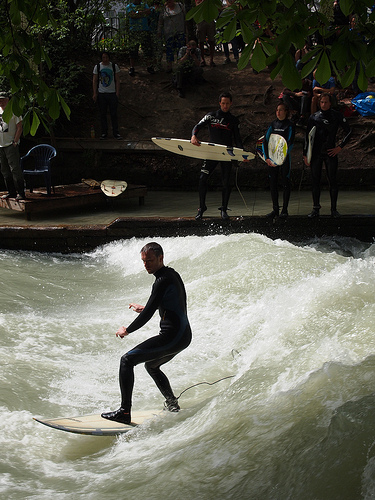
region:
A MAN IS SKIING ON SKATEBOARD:
[28, 236, 195, 435]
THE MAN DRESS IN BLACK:
[100, 241, 195, 422]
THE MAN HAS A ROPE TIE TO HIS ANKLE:
[160, 372, 238, 411]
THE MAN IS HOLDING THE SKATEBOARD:
[150, 134, 257, 163]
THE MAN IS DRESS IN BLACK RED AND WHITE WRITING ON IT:
[189, 91, 247, 221]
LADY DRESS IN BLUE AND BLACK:
[253, 102, 293, 224]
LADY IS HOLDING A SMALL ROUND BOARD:
[250, 132, 289, 169]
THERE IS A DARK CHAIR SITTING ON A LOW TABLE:
[18, 143, 57, 192]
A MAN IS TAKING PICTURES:
[171, 35, 208, 95]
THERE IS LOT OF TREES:
[0, 1, 374, 137]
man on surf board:
[24, 229, 227, 441]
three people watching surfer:
[141, 86, 359, 223]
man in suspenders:
[84, 48, 130, 143]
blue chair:
[14, 137, 62, 197]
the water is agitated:
[193, 222, 374, 448]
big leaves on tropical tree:
[222, 36, 374, 89]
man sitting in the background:
[173, 36, 213, 96]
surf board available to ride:
[79, 163, 144, 212]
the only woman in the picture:
[250, 93, 305, 229]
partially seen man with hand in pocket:
[1, 82, 32, 205]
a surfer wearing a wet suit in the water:
[97, 232, 200, 432]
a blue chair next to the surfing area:
[11, 136, 63, 196]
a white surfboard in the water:
[27, 401, 170, 443]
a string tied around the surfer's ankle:
[163, 380, 251, 407]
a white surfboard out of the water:
[96, 168, 129, 200]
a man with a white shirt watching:
[81, 46, 138, 154]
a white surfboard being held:
[148, 122, 258, 178]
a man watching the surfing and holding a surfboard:
[306, 90, 362, 220]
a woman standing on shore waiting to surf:
[253, 96, 299, 218]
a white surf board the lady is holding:
[257, 133, 293, 170]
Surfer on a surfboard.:
[31, 242, 193, 436]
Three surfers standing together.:
[150, 84, 358, 221]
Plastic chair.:
[18, 142, 58, 195]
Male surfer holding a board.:
[151, 90, 256, 222]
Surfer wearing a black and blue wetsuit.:
[254, 98, 296, 219]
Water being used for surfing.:
[0, 237, 374, 499]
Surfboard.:
[98, 177, 128, 198]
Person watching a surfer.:
[88, 50, 123, 142]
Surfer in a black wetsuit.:
[95, 241, 194, 424]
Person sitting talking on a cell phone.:
[173, 39, 204, 99]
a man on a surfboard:
[28, 241, 216, 436]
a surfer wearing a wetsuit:
[97, 238, 200, 428]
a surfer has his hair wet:
[111, 239, 195, 413]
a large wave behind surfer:
[44, 231, 369, 478]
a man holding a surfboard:
[154, 91, 253, 224]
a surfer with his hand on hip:
[304, 93, 354, 225]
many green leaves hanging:
[180, 4, 372, 90]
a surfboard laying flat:
[99, 174, 126, 200]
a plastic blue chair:
[20, 144, 61, 197]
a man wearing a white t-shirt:
[0, 90, 19, 152]